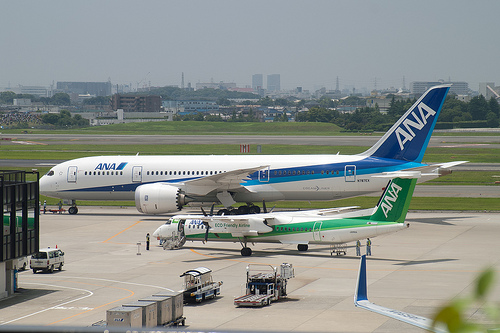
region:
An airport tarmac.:
[45, 72, 470, 293]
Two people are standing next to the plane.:
[347, 232, 377, 262]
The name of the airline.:
[375, 95, 451, 157]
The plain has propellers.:
[185, 190, 285, 250]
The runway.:
[10, 116, 370, 151]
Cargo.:
[85, 275, 200, 327]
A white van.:
[25, 235, 70, 285]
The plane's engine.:
[125, 160, 245, 215]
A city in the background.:
[31, 61, 411, 131]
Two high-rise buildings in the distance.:
[245, 67, 285, 97]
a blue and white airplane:
[39, 82, 448, 213]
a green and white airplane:
[150, 174, 420, 253]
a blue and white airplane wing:
[345, 246, 440, 331]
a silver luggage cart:
[103, 286, 188, 331]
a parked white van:
[26, 247, 66, 277]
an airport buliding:
[0, 164, 42, 299]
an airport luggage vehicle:
[238, 259, 293, 311]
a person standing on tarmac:
[142, 230, 152, 252]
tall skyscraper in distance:
[246, 71, 263, 91]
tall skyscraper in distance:
[263, 71, 279, 90]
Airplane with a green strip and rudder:
[161, 183, 419, 255]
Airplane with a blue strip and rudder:
[38, 83, 457, 207]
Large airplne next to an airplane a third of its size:
[41, 83, 469, 260]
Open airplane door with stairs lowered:
[158, 215, 190, 253]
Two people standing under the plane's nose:
[40, 195, 70, 216]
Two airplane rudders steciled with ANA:
[367, 80, 453, 250]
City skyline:
[5, 61, 495, 151]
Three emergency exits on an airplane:
[130, 161, 372, 191]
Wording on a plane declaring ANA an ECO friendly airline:
[206, 180, 446, 230]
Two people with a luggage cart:
[322, 237, 378, 257]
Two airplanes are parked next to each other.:
[23, 58, 474, 271]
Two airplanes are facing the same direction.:
[0, 63, 474, 262]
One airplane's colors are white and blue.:
[22, 65, 474, 224]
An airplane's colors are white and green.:
[145, 162, 429, 265]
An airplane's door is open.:
[144, 199, 206, 254]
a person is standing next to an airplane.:
[134, 219, 156, 263]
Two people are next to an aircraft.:
[340, 228, 387, 261]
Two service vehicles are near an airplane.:
[168, 244, 315, 312]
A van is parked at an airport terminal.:
[21, 241, 71, 282]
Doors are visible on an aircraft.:
[58, 158, 369, 191]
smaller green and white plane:
[150, 170, 435, 253]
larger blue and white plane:
[40, 79, 466, 219]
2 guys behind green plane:
[351, 235, 376, 255]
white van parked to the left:
[31, 245, 66, 272]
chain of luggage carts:
[100, 290, 188, 332]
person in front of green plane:
[143, 230, 150, 252]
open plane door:
[158, 215, 188, 250]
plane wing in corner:
[353, 253, 458, 331]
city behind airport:
[1, 64, 498, 123]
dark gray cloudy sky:
[1, 0, 498, 91]